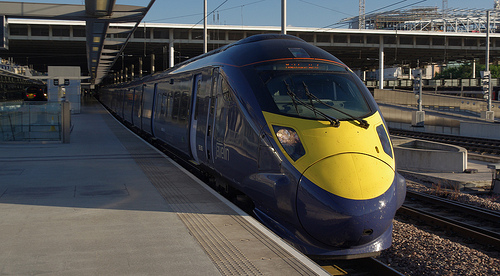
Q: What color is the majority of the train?
A: Blue.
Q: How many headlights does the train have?
A: Two.